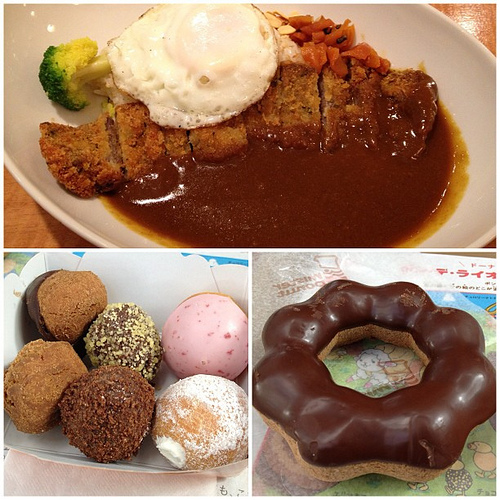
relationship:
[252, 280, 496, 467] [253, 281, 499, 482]
frosting on top of crueller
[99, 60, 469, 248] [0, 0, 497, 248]
gravy on top of plate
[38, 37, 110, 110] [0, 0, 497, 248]
broccoli on top of plate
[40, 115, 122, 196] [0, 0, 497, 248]
piece of meat on top of plate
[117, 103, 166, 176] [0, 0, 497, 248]
piece of meat on top of plate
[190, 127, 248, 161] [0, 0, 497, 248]
piece of meat on top of plate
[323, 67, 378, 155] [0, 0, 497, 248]
piece of meat on top of plate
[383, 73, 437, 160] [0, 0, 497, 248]
piece of meat on top of plate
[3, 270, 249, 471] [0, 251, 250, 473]
donut holes are inside of paper bowl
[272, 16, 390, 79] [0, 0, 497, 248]
tomato on top of plate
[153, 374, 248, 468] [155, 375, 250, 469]
powdered sugar on top of doughnut hole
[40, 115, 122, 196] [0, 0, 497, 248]
meat on top of plate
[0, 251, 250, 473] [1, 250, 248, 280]
box has edge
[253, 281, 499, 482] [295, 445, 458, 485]
doughnut has edge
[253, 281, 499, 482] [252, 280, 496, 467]
doughnut has chocolate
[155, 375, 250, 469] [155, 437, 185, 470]
donut hole has cream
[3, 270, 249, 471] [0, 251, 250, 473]
donuts are inside of paper bowl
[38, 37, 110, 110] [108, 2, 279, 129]
broccoli next to egg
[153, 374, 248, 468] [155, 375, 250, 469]
powdered sugar on top of donut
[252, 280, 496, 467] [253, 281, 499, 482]
chocolate on top of donut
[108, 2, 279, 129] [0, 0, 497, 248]
fried egg on top of plate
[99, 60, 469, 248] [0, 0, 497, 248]
sauce inside of dish